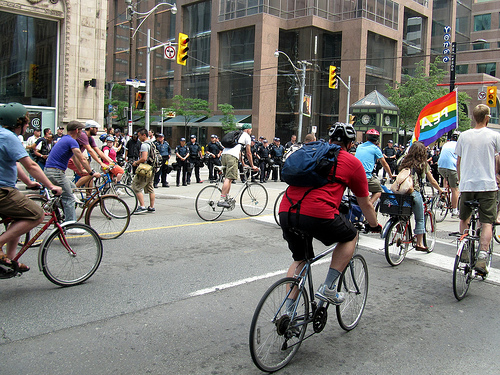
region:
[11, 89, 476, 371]
people riding the bikes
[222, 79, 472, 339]
people riding the bikes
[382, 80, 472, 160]
the flag is coloful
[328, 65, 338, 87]
yellow traffic light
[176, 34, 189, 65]
yellow traffic light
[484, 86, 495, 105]
yellow traffic light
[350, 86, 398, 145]
small green clock tower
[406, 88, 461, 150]
rainbow flag held by a bike rider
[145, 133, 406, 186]
row of police officers standing beside road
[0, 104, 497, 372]
group of bikeriders going down a street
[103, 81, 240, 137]
row of trees beside road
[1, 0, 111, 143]
tall grey concrete building beside road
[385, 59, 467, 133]
tree standing beside road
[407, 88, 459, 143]
rainbow flag with white text on it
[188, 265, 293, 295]
white paint on the ground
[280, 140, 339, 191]
blue back pack on the man's back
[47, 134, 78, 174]
blue tee shirt on the man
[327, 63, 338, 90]
yellow framed stop light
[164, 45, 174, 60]
red and white metal street sign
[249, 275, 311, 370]
bike's rear wheel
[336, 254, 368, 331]
bike's front wheel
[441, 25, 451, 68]
business sign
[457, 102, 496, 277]
the man is standing on the bike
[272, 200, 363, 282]
he is siding the bike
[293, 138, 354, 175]
he is carrying the pack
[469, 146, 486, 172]
the shirt is white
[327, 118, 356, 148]
he is wearing a helmet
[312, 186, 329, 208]
the shirt is red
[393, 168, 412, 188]
the pack is tan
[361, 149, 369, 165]
the shirt is torquoise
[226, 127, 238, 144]
the pack is black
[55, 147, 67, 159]
the shirt is blue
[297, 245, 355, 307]
the bike is silver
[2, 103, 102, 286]
person sitting on bike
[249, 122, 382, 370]
person sitting on bike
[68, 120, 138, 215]
person sitting on bike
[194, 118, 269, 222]
person standing on bike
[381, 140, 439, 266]
person sitting on bike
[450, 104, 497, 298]
person standing on bike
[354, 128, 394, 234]
person sitting on bike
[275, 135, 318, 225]
person sitting on bike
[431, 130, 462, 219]
person sitting on bike